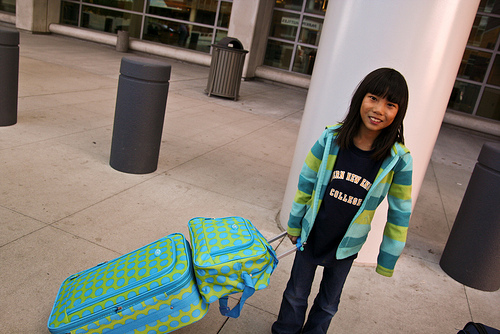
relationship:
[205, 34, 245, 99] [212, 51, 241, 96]
can has lines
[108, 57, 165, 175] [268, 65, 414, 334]
cylinders behind girl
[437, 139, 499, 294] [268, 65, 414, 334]
cylinders behind girl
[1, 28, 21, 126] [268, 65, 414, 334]
cylinders behind girl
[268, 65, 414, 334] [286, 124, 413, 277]
girl wearing clothing (implied)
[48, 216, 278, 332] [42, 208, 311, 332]
dots on luggage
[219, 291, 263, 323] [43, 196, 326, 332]
strap on luggage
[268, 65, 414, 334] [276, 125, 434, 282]
girl wearing jacket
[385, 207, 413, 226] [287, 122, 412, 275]
stripe on jacket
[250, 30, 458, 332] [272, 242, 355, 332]
girl wearing jeans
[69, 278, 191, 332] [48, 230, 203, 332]
zipper on luggage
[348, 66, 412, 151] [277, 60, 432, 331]
head of person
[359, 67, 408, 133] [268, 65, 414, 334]
head of girl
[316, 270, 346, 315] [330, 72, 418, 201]
leg of person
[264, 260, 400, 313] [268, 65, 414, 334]
leg of a girl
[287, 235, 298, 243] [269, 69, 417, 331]
hand of a person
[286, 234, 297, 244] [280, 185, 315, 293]
hand of a person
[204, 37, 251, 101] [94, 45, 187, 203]
dust bin a dust bin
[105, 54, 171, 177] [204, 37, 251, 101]
pillar a dust bin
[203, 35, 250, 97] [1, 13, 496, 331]
trash barrel outside airport on sidewalk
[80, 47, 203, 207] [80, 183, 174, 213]
pillar on a sidewalk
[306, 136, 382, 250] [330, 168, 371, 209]
shirt with letters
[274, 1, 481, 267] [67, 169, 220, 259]
pillar on a sidewalk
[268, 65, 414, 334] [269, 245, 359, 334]
girl wearing jeans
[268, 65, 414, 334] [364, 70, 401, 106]
girl with black hair and bangs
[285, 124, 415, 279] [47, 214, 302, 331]
sweater matches suitcase